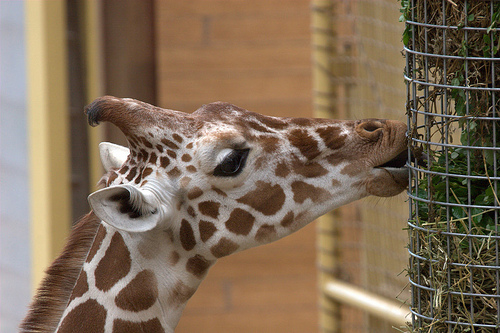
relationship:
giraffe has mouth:
[26, 93, 425, 332] [377, 139, 416, 189]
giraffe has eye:
[26, 93, 425, 332] [204, 138, 252, 181]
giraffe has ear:
[26, 93, 425, 332] [89, 180, 176, 235]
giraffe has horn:
[26, 93, 425, 332] [85, 95, 188, 148]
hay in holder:
[395, 0, 499, 326] [402, 3, 499, 326]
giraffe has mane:
[26, 93, 425, 332] [18, 207, 101, 331]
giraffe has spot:
[26, 93, 425, 332] [315, 122, 349, 150]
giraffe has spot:
[26, 93, 425, 332] [284, 123, 324, 167]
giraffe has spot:
[26, 93, 425, 332] [285, 150, 329, 180]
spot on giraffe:
[275, 154, 291, 179] [26, 93, 425, 332]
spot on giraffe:
[290, 177, 330, 207] [26, 93, 425, 332]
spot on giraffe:
[281, 207, 298, 225] [26, 93, 425, 332]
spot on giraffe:
[235, 175, 287, 215] [26, 93, 425, 332]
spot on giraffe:
[223, 203, 257, 238] [26, 93, 425, 332]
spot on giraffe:
[195, 200, 221, 220] [26, 93, 425, 332]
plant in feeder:
[406, 11, 498, 330] [399, 6, 488, 329]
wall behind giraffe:
[160, 11, 410, 324] [26, 93, 425, 332]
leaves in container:
[399, 6, 498, 321] [401, 0, 500, 332]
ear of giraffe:
[100, 139, 127, 174] [26, 93, 425, 332]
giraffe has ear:
[26, 93, 425, 332] [85, 182, 174, 233]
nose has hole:
[343, 113, 409, 141] [362, 123, 380, 132]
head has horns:
[71, 97, 409, 261] [79, 95, 189, 143]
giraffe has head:
[26, 93, 425, 332] [71, 97, 409, 261]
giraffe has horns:
[26, 93, 425, 332] [79, 95, 189, 143]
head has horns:
[71, 97, 409, 261] [84, 95, 183, 140]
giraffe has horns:
[26, 93, 425, 332] [84, 95, 183, 140]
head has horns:
[71, 97, 409, 261] [84, 95, 188, 148]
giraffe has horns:
[26, 93, 425, 332] [84, 95, 188, 148]